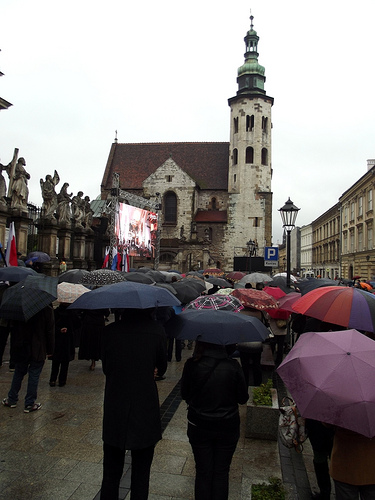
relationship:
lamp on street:
[278, 197, 301, 233] [290, 251, 373, 500]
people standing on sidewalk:
[2, 252, 375, 499] [4, 267, 317, 500]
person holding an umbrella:
[176, 309, 264, 498] [173, 307, 271, 355]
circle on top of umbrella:
[343, 349, 355, 359] [276, 327, 375, 437]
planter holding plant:
[246, 384, 280, 438] [252, 379, 276, 408]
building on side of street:
[96, 7, 284, 271] [290, 251, 373, 500]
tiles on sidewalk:
[147, 370, 188, 435] [4, 267, 317, 500]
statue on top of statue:
[8, 148, 32, 209] [38, 171, 64, 278]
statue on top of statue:
[40, 171, 65, 217] [38, 171, 64, 278]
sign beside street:
[263, 246, 279, 267] [290, 251, 373, 500]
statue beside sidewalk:
[8, 148, 32, 209] [4, 267, 317, 500]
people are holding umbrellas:
[2, 252, 375, 499] [2, 248, 375, 441]